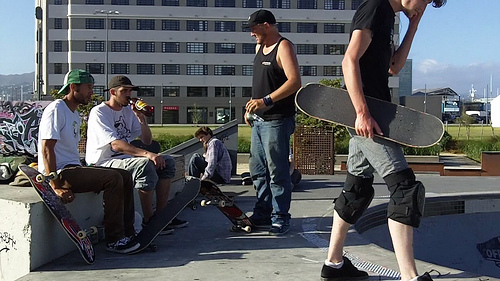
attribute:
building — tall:
[30, 0, 404, 127]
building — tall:
[395, 56, 412, 99]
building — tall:
[396, 89, 444, 121]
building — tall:
[488, 89, 498, 131]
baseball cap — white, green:
[57, 69, 97, 92]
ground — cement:
[194, 234, 274, 266]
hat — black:
[240, 8, 274, 30]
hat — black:
[103, 75, 133, 92]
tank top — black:
[255, 45, 283, 82]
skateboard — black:
[290, 77, 449, 154]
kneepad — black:
[384, 168, 443, 239]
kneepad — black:
[336, 166, 371, 223]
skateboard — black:
[120, 168, 228, 259]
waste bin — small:
[298, 123, 335, 179]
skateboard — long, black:
[273, 58, 470, 169]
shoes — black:
[311, 246, 362, 277]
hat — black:
[234, 4, 294, 29]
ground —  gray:
[106, 258, 308, 279]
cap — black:
[237, 7, 282, 34]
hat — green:
[51, 67, 100, 94]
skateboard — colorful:
[17, 159, 106, 264]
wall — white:
[0, 122, 244, 278]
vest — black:
[248, 36, 298, 116]